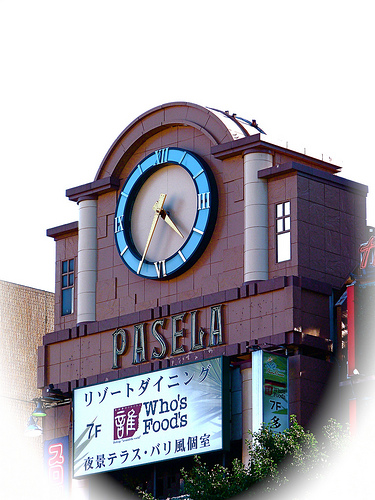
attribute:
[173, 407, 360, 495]
tree — old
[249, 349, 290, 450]
sign — green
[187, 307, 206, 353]
letter — large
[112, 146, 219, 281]
border — blue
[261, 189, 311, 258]
window — skinny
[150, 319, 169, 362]
letter — large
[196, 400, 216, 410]
sign — white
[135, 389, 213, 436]
writing — black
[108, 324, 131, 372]
letter — large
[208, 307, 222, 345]
letter — large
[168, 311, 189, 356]
letter — large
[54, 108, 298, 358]
wall — brick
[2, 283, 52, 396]
wall — brick